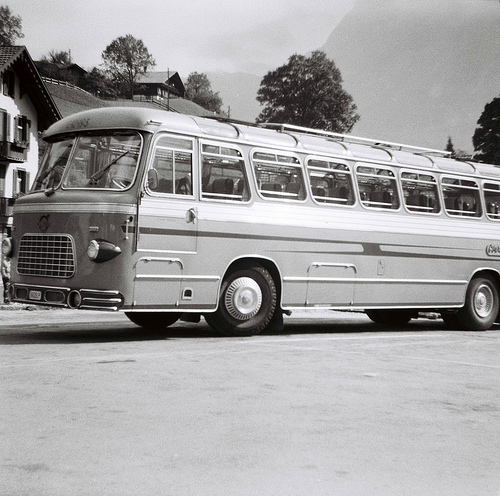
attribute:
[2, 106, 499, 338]
bus — parked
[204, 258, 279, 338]
wheel — black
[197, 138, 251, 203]
window — open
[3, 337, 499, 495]
road — gray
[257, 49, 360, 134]
tree — leafy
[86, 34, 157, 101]
tree — leafy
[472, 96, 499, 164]
tree — leafy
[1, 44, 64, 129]
roof — brown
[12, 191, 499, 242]
stripe — white